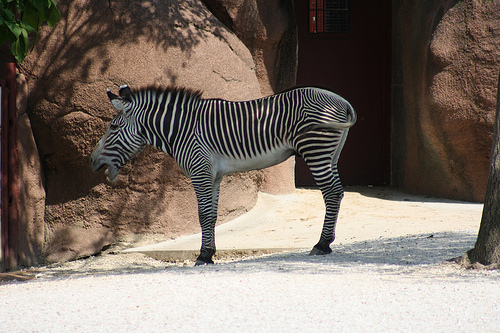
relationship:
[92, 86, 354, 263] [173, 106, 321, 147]
zebra has stripes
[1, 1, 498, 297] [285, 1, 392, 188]
pen has a doorway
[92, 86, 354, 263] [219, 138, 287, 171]
zebra has an underbelly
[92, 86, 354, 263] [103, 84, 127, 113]
zebra has an ear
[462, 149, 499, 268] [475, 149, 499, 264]
tree has a tree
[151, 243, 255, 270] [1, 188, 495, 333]
grate on ground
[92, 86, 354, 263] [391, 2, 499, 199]
zebra near rock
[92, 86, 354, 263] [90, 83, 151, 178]
zebra has a head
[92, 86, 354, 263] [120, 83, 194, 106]
zebra has a mane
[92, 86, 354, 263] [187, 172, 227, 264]
zebra has legs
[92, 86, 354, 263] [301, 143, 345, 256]
zebra has hind legs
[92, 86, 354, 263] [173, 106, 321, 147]
zebra with stripes